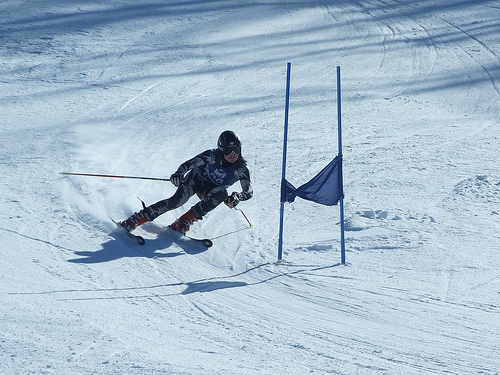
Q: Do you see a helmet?
A: Yes, there is a helmet.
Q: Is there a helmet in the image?
A: Yes, there is a helmet.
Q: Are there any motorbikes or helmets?
A: Yes, there is a helmet.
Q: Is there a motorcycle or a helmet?
A: Yes, there is a helmet.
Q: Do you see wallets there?
A: No, there are no wallets.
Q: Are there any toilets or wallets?
A: No, there are no wallets or toilets.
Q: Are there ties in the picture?
A: No, there are no ties.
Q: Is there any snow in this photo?
A: Yes, there is snow.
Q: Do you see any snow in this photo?
A: Yes, there is snow.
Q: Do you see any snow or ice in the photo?
A: Yes, there is snow.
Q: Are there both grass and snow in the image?
A: No, there is snow but no grass.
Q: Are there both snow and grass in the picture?
A: No, there is snow but no grass.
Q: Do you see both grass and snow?
A: No, there is snow but no grass.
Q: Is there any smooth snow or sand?
A: Yes, there is smooth snow.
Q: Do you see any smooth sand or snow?
A: Yes, there is smooth snow.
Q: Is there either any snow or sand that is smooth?
A: Yes, the snow is smooth.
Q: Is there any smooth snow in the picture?
A: Yes, there is smooth snow.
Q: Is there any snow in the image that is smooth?
A: Yes, there is snow that is smooth.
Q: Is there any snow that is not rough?
A: Yes, there is smooth snow.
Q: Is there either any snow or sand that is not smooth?
A: No, there is snow but it is smooth.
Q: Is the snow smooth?
A: Yes, the snow is smooth.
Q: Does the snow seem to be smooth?
A: Yes, the snow is smooth.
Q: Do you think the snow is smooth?
A: Yes, the snow is smooth.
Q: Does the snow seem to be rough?
A: No, the snow is smooth.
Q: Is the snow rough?
A: No, the snow is smooth.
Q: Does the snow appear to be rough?
A: No, the snow is smooth.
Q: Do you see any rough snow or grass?
A: No, there is snow but it is smooth.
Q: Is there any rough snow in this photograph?
A: No, there is snow but it is smooth.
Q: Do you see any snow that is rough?
A: No, there is snow but it is smooth.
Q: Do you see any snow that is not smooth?
A: No, there is snow but it is smooth.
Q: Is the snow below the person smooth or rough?
A: The snow is smooth.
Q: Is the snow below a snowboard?
A: No, the snow is below a person.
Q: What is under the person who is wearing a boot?
A: The snow is under the person.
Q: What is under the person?
A: The snow is under the person.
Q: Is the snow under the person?
A: Yes, the snow is under the person.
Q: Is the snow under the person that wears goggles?
A: Yes, the snow is under the person.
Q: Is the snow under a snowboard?
A: No, the snow is under the person.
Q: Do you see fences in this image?
A: No, there are no fences.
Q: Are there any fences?
A: No, there are no fences.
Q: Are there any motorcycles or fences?
A: No, there are no fences or motorcycles.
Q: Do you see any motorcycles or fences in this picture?
A: No, there are no fences or motorcycles.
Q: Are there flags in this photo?
A: Yes, there is a flag.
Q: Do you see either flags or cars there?
A: Yes, there is a flag.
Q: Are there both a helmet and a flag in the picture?
A: Yes, there are both a flag and a helmet.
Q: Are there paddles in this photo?
A: No, there are no paddles.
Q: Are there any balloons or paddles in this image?
A: No, there are no paddles or balloons.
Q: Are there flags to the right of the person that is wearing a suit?
A: Yes, there is a flag to the right of the person.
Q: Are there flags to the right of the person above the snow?
A: Yes, there is a flag to the right of the person.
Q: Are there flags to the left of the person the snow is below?
A: No, the flag is to the right of the person.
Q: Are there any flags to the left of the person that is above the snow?
A: No, the flag is to the right of the person.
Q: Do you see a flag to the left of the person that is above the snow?
A: No, the flag is to the right of the person.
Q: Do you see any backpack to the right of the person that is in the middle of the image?
A: No, there is a flag to the right of the person.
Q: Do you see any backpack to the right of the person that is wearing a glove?
A: No, there is a flag to the right of the person.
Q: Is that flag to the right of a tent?
A: No, the flag is to the right of a person.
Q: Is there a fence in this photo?
A: No, there are no fences.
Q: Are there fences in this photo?
A: No, there are no fences.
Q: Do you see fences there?
A: No, there are no fences.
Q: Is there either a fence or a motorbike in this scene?
A: No, there are no fences or motorcycles.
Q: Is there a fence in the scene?
A: No, there are no fences.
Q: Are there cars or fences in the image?
A: No, there are no fences or cars.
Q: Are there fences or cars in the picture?
A: No, there are no fences or cars.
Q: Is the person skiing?
A: Yes, the person is skiing.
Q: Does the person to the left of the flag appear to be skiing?
A: Yes, the person is skiing.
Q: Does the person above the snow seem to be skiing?
A: Yes, the person is skiing.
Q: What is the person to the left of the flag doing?
A: The person is skiing.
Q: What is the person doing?
A: The person is skiing.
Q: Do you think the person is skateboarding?
A: No, the person is skiing.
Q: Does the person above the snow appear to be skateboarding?
A: No, the person is skiing.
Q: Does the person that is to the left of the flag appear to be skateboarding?
A: No, the person is skiing.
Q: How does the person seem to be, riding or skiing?
A: The person is skiing.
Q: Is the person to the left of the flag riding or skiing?
A: The person is skiing.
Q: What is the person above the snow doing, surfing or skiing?
A: The person is skiing.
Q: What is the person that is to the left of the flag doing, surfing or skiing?
A: The person is skiing.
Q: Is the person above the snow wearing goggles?
A: Yes, the person is wearing goggles.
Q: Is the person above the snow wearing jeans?
A: No, the person is wearing goggles.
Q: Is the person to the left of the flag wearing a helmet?
A: Yes, the person is wearing a helmet.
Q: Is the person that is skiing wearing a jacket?
A: No, the person is wearing a helmet.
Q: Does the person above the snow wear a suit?
A: Yes, the person wears a suit.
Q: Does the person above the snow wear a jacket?
A: No, the person wears a suit.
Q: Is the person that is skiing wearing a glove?
A: Yes, the person is wearing a glove.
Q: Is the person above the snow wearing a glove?
A: Yes, the person is wearing a glove.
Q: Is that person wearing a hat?
A: No, the person is wearing a glove.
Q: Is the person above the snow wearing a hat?
A: No, the person is wearing a glove.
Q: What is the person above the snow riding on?
A: The person is riding on the skis.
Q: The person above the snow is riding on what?
A: The person is riding on the skis.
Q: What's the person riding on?
A: The person is riding on the skis.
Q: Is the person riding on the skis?
A: Yes, the person is riding on the skis.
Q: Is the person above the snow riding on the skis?
A: Yes, the person is riding on the skis.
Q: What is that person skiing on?
A: The person is skiing on the snow.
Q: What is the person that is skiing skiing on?
A: The person is skiing on the snow.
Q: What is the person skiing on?
A: The person is skiing on the snow.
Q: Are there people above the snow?
A: Yes, there is a person above the snow.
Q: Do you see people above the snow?
A: Yes, there is a person above the snow.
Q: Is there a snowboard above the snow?
A: No, there is a person above the snow.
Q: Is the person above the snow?
A: Yes, the person is above the snow.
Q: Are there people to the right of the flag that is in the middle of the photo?
A: No, the person is to the left of the flag.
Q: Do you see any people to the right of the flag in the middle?
A: No, the person is to the left of the flag.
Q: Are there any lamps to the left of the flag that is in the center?
A: No, there is a person to the left of the flag.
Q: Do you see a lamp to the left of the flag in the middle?
A: No, there is a person to the left of the flag.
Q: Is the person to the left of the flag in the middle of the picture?
A: Yes, the person is to the left of the flag.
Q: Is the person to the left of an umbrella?
A: No, the person is to the left of the flag.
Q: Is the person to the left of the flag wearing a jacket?
A: No, the person is wearing a boot.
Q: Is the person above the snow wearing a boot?
A: Yes, the person is wearing a boot.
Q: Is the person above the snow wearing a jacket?
A: No, the person is wearing a boot.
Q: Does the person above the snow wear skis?
A: Yes, the person wears skis.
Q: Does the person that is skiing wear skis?
A: Yes, the person wears skis.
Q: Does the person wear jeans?
A: No, the person wears skis.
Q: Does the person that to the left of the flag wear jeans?
A: No, the person wears skis.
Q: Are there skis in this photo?
A: Yes, there are skis.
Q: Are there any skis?
A: Yes, there are skis.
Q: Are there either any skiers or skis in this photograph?
A: Yes, there are skis.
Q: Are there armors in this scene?
A: No, there are no armors.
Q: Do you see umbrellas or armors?
A: No, there are no armors or umbrellas.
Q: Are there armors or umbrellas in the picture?
A: No, there are no armors or umbrellas.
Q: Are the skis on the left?
A: Yes, the skis are on the left of the image.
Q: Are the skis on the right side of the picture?
A: No, the skis are on the left of the image.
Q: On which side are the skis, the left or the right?
A: The skis are on the left of the image.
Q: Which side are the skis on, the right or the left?
A: The skis are on the left of the image.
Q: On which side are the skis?
A: The skis are on the left of the image.